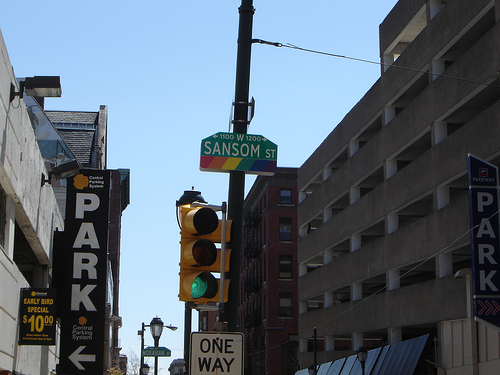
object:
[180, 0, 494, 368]
building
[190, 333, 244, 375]
sign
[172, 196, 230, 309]
traffic sign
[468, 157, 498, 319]
sign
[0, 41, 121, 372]
building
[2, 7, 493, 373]
street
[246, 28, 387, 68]
power line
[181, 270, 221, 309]
signal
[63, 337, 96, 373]
arrow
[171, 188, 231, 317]
traffic sigal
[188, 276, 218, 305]
light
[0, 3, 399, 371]
sky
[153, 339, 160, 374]
pole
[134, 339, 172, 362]
base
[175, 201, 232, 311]
stoplight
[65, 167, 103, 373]
sign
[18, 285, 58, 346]
sign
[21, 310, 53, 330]
price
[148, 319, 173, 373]
lamp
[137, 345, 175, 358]
sign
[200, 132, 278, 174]
sign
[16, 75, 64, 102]
light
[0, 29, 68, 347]
garage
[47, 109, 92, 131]
roof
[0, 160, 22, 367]
area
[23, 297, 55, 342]
special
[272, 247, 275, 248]
bricks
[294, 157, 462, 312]
structure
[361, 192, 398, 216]
concrete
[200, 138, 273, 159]
name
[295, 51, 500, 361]
garage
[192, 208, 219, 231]
light